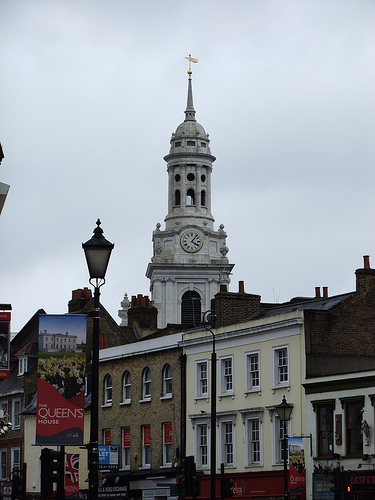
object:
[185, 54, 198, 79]
weather vane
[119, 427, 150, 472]
white shades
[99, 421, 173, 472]
windows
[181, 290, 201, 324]
archway window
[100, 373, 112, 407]
curved window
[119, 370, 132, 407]
curved window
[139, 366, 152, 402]
curved window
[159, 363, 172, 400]
curved window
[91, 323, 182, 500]
building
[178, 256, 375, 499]
building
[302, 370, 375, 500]
building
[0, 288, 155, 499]
building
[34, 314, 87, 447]
sign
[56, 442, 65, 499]
pole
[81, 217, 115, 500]
lamp post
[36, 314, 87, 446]
queens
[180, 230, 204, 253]
clock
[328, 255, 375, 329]
roof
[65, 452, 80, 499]
flag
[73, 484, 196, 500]
road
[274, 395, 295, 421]
lamp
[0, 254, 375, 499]
building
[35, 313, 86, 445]
advertising banner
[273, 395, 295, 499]
lamp post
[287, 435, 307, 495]
advertising banner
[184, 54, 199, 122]
steeple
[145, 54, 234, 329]
clock tower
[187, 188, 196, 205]
window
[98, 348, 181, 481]
building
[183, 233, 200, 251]
numerals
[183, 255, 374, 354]
roof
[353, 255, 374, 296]
chimney